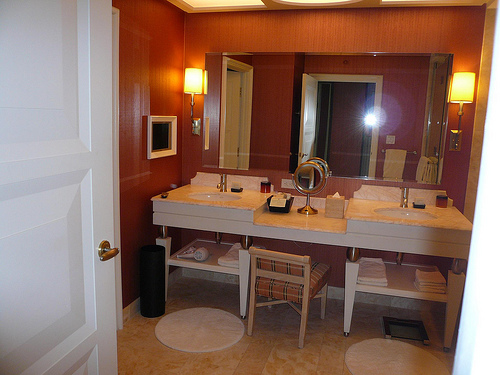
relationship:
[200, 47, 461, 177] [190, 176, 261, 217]
mirror on sink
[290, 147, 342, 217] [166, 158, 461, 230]
mirror on sink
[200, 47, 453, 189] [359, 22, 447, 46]
mirror on wall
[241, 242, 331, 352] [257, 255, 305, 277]
chair with cushions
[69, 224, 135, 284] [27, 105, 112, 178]
handle on door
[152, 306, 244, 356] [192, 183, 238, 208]
rug beneath sink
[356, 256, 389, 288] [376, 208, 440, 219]
towel beneath sink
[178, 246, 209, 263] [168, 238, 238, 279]
blow dryer on shelf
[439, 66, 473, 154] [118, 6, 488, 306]
lamp on wall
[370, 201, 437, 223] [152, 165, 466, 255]
sink on counter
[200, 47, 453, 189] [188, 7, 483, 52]
mirror on wall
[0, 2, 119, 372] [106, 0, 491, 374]
door into room